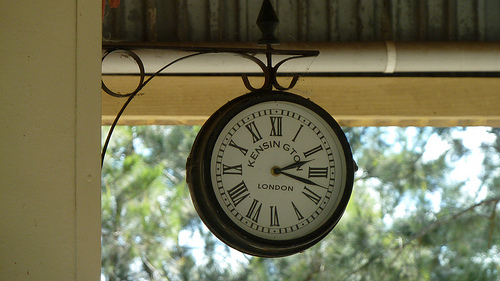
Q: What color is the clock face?
A: White.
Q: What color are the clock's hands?
A: Black.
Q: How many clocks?
A: One.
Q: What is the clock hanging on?
A: A pole.